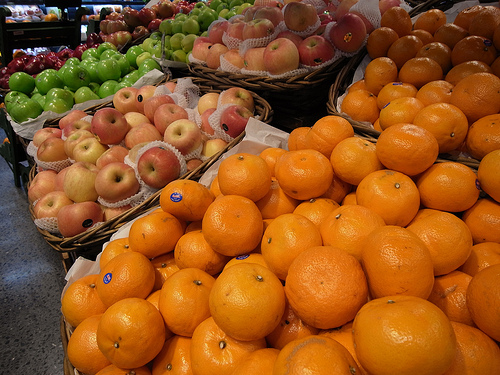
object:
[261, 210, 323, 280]
orange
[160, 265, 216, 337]
orange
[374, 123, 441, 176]
orange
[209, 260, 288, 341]
orange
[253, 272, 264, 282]
stem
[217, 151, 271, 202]
orange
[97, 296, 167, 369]
orange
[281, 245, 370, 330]
fruit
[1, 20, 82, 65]
table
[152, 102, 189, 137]
apple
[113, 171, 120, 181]
stem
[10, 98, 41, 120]
apple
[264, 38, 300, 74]
apples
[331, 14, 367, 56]
apples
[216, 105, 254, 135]
apples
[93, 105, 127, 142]
apples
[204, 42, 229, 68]
apples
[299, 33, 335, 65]
apples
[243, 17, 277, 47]
apples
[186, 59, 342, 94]
basket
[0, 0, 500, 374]
display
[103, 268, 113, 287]
sticker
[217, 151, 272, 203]
apples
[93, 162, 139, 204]
apples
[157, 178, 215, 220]
oranges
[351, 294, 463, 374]
orange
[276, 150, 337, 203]
orange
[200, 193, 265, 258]
orange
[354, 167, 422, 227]
fruit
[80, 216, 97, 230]
sticker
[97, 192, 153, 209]
cup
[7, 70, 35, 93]
apple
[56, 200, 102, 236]
apple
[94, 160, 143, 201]
apple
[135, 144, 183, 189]
apple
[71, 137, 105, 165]
apple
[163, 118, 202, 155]
apple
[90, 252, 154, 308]
orange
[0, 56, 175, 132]
bin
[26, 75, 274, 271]
basket